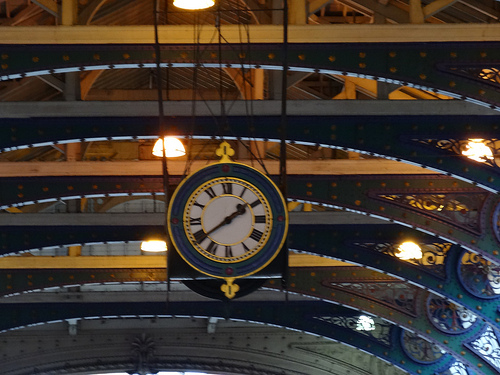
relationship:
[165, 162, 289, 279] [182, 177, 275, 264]
clock has clock face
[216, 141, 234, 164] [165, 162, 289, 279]
decoration on clock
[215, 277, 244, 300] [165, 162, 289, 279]
decoration on clock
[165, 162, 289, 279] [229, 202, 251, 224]
clock has hand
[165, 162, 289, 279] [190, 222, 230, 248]
clock has hand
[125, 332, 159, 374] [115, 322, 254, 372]
artwork on entrance arch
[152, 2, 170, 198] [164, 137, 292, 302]
hanger rod for clock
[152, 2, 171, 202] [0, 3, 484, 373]
hanger rod suspended from ceiling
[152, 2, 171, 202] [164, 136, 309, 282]
hanger rod of clock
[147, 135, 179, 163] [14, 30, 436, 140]
light below ceiling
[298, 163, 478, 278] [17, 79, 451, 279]
ceiling has arch supports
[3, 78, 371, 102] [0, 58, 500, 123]
ceiling has arch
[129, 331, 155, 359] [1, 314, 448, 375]
artwork on arch supports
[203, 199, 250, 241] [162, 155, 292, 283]
hand on clock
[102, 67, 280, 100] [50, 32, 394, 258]
decorative bands are on ceiling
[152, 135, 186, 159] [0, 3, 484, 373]
light below ceiling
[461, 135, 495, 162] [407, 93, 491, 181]
light below ceiling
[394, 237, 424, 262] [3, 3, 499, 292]
light below ceiling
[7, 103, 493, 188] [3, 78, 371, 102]
arch supporting ceiling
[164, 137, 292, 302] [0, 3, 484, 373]
clock hanging from ceiling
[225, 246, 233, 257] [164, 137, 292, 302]
number are on clock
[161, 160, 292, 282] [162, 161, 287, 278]
frame on clock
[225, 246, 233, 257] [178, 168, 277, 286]
number are on clock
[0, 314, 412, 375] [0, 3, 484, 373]
support decorating ceiling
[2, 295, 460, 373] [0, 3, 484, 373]
support decorating ceiling